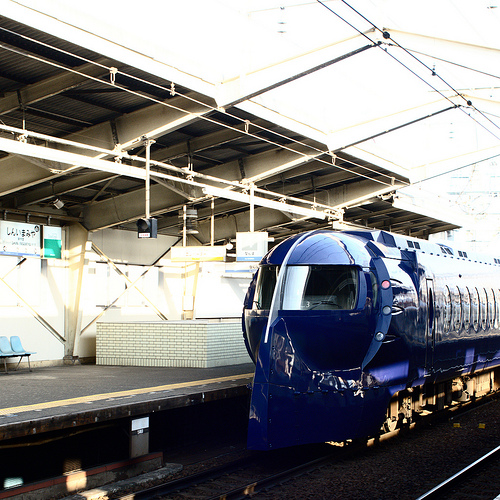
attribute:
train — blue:
[274, 229, 497, 467]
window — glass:
[455, 283, 483, 346]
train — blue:
[240, 218, 498, 475]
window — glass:
[469, 276, 493, 338]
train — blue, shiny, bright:
[234, 221, 497, 457]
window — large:
[280, 263, 363, 308]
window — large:
[236, 260, 278, 318]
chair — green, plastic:
[8, 331, 34, 368]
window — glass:
[240, 264, 280, 312]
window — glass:
[279, 263, 359, 312]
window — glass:
[440, 286, 453, 326]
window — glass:
[451, 286, 469, 336]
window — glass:
[465, 283, 478, 330]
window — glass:
[480, 285, 492, 337]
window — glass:
[456, 247, 467, 261]